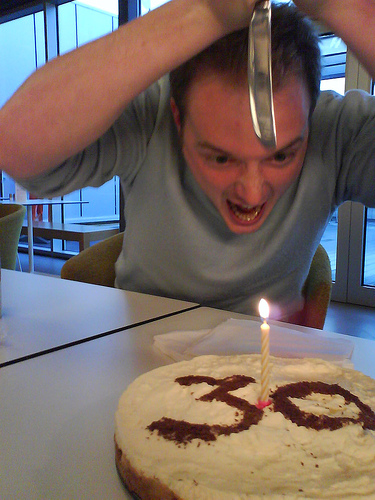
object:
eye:
[267, 147, 300, 164]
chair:
[59, 228, 336, 329]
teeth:
[234, 210, 241, 216]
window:
[74, 0, 114, 47]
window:
[0, 8, 37, 109]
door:
[346, 31, 375, 308]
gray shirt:
[15, 70, 375, 324]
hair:
[168, 3, 324, 133]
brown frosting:
[148, 372, 375, 447]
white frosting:
[225, 351, 326, 366]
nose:
[233, 160, 268, 205]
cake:
[117, 296, 375, 498]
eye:
[199, 140, 237, 176]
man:
[0, 0, 375, 321]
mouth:
[228, 197, 269, 227]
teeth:
[246, 216, 253, 223]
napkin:
[151, 311, 354, 367]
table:
[0, 260, 373, 494]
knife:
[247, 1, 283, 150]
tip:
[255, 123, 279, 149]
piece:
[256, 399, 273, 407]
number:
[147, 366, 373, 447]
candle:
[258, 323, 273, 409]